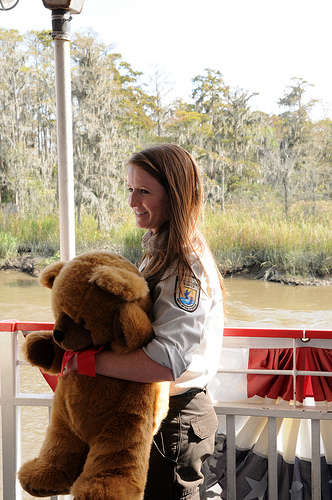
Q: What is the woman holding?
A: Teddy bear.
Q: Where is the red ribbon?
A: Around bear's neck.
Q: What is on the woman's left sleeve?
A: Patch.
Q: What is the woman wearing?
A: Uniform.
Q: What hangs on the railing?
A: American flag bunting.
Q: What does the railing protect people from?
A: Water.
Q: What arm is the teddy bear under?
A: Left.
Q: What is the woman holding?
A: A teddy bear.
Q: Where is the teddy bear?
A: In the woman's arms.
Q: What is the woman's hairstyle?
A: Long and straight.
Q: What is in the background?
A: A swamp.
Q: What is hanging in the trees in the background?
A: Spanish moss.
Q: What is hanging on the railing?
A: A flag.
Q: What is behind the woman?
A: Railing.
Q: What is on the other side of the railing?
A: Water.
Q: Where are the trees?
A: In the swamp.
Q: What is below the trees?
A: Tall grass.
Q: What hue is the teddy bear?
A: Brown.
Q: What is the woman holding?
A: A teddy bear.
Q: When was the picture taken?
A: Daytime.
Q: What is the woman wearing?
A: A uniform.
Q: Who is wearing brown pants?
A: The woman.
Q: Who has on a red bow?
A: Stuffed animal.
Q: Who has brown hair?
A: Woman.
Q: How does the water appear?
A: Murky.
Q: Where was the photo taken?
A: Near a river.